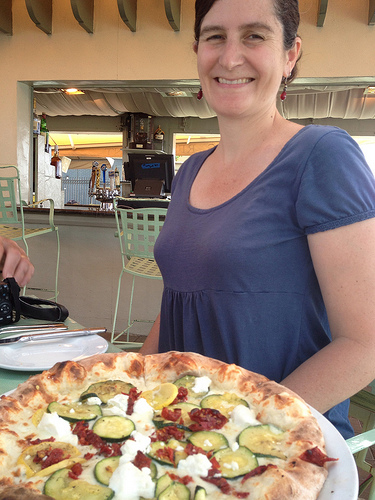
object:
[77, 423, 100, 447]
tomato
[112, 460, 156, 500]
goat cheese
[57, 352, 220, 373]
crust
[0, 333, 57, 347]
knives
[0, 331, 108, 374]
plate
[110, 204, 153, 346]
stools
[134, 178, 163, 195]
back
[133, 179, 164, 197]
computer monitor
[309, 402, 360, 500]
platter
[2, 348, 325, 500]
pizza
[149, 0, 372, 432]
lady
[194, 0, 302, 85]
hair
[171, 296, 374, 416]
torso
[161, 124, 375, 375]
shirt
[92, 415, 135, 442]
zucchini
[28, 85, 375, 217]
kitchen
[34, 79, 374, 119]
awning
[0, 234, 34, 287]
hand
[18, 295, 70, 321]
strap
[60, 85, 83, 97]
light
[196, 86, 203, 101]
earrings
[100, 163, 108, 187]
beer taps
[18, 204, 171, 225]
bar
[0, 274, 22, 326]
camera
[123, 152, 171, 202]
cash register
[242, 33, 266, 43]
eye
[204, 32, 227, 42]
eye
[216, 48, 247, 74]
nose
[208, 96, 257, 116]
chin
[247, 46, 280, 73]
cheek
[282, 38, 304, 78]
ear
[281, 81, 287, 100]
earring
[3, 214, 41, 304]
person